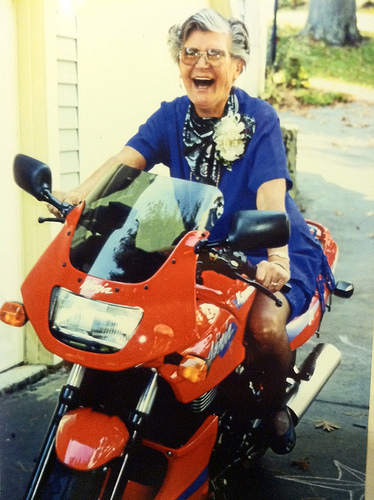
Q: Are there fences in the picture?
A: No, there are no fences.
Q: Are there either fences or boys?
A: No, there are no fences or boys.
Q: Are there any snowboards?
A: No, there are no snowboards.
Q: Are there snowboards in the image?
A: No, there are no snowboards.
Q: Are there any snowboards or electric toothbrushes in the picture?
A: No, there are no snowboards or electric toothbrushes.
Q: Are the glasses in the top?
A: Yes, the glasses are in the top of the image.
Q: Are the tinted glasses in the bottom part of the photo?
A: No, the glasses are in the top of the image.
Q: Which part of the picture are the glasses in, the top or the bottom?
A: The glasses are in the top of the image.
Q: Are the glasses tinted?
A: Yes, the glasses are tinted.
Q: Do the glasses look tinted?
A: Yes, the glasses are tinted.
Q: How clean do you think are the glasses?
A: The glasses are tinted.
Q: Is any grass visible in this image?
A: Yes, there is grass.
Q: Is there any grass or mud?
A: Yes, there is grass.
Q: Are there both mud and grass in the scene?
A: No, there is grass but no mud.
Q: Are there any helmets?
A: No, there are no helmets.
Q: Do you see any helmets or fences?
A: No, there are no helmets or fences.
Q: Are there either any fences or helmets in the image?
A: No, there are no helmets or fences.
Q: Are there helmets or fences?
A: No, there are no helmets or fences.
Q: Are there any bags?
A: No, there are no bags.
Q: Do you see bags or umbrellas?
A: No, there are no bags or umbrellas.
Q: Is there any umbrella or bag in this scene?
A: No, there are no bags or umbrellas.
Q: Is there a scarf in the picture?
A: Yes, there is a scarf.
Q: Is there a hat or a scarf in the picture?
A: Yes, there is a scarf.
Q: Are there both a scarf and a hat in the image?
A: No, there is a scarf but no hats.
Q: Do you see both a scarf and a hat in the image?
A: No, there is a scarf but no hats.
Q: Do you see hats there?
A: No, there are no hats.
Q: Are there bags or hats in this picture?
A: No, there are no hats or bags.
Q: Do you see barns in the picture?
A: No, there are no barns.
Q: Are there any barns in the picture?
A: No, there are no barns.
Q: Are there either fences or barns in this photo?
A: No, there are no barns or fences.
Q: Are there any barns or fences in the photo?
A: No, there are no barns or fences.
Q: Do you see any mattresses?
A: No, there are no mattresses.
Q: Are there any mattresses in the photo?
A: No, there are no mattresses.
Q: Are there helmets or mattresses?
A: No, there are no mattresses or helmets.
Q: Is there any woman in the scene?
A: Yes, there is a woman.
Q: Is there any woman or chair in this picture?
A: Yes, there is a woman.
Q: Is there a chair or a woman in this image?
A: Yes, there is a woman.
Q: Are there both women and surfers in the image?
A: No, there is a woman but no surfers.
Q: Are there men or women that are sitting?
A: Yes, the woman is sitting.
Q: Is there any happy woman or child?
A: Yes, there is a happy woman.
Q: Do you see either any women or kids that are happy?
A: Yes, the woman is happy.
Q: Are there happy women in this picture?
A: Yes, there is a happy woman.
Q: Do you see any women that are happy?
A: Yes, there is a happy woman.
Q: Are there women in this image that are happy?
A: Yes, there is a woman that is happy.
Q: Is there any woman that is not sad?
A: Yes, there is a happy woman.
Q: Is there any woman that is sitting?
A: Yes, there is a woman that is sitting.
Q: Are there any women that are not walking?
A: Yes, there is a woman that is sitting.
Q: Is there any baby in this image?
A: No, there are no babies.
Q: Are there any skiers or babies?
A: No, there are no babies or skiers.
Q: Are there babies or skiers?
A: No, there are no babies or skiers.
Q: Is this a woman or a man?
A: This is a woman.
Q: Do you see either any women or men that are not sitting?
A: No, there is a woman but she is sitting.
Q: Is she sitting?
A: Yes, the woman is sitting.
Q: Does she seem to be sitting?
A: Yes, the woman is sitting.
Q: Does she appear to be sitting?
A: Yes, the woman is sitting.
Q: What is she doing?
A: The woman is sitting.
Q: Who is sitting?
A: The woman is sitting.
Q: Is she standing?
A: No, the woman is sitting.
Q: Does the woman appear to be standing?
A: No, the woman is sitting.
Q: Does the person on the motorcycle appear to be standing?
A: No, the woman is sitting.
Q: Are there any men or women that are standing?
A: No, there is a woman but she is sitting.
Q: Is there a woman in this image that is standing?
A: No, there is a woman but she is sitting.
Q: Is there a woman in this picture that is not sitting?
A: No, there is a woman but she is sitting.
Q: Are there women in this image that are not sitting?
A: No, there is a woman but she is sitting.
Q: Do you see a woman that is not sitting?
A: No, there is a woman but she is sitting.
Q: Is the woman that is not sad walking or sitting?
A: The woman is sitting.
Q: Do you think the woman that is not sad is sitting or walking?
A: The woman is sitting.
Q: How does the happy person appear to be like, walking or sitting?
A: The woman is sitting.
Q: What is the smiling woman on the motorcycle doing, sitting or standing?
A: The woman is sitting.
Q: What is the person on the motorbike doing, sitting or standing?
A: The woman is sitting.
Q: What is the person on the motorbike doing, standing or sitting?
A: The woman is sitting.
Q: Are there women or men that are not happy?
A: No, there is a woman but she is happy.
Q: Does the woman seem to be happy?
A: Yes, the woman is happy.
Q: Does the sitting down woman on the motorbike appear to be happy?
A: Yes, the woman is happy.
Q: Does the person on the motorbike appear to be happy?
A: Yes, the woman is happy.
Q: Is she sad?
A: No, the woman is happy.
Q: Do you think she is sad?
A: No, the woman is happy.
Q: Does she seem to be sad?
A: No, the woman is happy.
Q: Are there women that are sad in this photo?
A: No, there is a woman but she is happy.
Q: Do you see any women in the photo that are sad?
A: No, there is a woman but she is happy.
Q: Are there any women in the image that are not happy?
A: No, there is a woman but she is happy.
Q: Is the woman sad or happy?
A: The woman is happy.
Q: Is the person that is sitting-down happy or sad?
A: The woman is happy.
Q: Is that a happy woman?
A: Yes, that is a happy woman.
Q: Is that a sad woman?
A: No, that is a happy woman.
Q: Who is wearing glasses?
A: The woman is wearing glasses.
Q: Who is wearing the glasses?
A: The woman is wearing glasses.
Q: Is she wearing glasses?
A: Yes, the woman is wearing glasses.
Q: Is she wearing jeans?
A: No, the woman is wearing glasses.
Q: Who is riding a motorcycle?
A: The woman is riding a motorcycle.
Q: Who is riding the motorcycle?
A: The woman is riding a motorcycle.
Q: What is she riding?
A: The woman is riding a motorcycle.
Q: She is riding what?
A: The woman is riding a motorcycle.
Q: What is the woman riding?
A: The woman is riding a motorcycle.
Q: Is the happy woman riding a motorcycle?
A: Yes, the woman is riding a motorcycle.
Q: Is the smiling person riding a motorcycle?
A: Yes, the woman is riding a motorcycle.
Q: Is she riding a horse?
A: No, the woman is riding a motorcycle.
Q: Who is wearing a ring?
A: The woman is wearing a ring.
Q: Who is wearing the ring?
A: The woman is wearing a ring.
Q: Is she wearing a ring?
A: Yes, the woman is wearing a ring.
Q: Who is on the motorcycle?
A: The woman is on the motorcycle.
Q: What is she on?
A: The woman is on the motorcycle.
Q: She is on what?
A: The woman is on the motorcycle.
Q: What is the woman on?
A: The woman is on the motorcycle.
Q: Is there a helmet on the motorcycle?
A: No, there is a woman on the motorcycle.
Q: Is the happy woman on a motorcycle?
A: Yes, the woman is on a motorcycle.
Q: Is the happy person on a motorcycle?
A: Yes, the woman is on a motorcycle.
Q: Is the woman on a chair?
A: No, the woman is on a motorcycle.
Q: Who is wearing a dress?
A: The woman is wearing a dress.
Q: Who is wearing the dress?
A: The woman is wearing a dress.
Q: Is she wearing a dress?
A: Yes, the woman is wearing a dress.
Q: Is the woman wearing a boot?
A: No, the woman is wearing a dress.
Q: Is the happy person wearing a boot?
A: No, the woman is wearing a dress.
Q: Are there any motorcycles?
A: Yes, there is a motorcycle.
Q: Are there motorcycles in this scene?
A: Yes, there is a motorcycle.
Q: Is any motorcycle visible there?
A: Yes, there is a motorcycle.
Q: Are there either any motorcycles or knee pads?
A: Yes, there is a motorcycle.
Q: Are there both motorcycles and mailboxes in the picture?
A: No, there is a motorcycle but no mailboxes.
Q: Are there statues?
A: No, there are no statues.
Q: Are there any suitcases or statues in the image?
A: No, there are no statues or suitcases.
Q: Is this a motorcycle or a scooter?
A: This is a motorcycle.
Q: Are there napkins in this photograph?
A: No, there are no napkins.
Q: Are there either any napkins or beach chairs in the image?
A: No, there are no napkins or beach chairs.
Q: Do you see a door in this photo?
A: Yes, there is a door.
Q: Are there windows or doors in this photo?
A: Yes, there is a door.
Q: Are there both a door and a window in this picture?
A: No, there is a door but no windows.